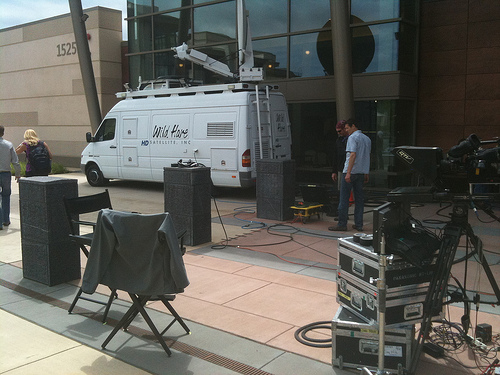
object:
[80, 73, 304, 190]
truck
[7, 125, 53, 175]
woman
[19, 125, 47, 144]
blonde hair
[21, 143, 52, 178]
bookbag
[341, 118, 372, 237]
man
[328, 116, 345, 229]
man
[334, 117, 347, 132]
bandana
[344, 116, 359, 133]
black hair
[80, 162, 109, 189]
front wheel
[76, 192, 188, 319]
coat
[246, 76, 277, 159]
ladder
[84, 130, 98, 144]
mirror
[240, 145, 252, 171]
brake light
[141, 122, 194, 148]
words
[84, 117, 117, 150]
window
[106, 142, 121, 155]
door handle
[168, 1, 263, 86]
antennae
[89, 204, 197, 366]
chair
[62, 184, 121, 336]
chair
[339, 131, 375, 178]
blue shirt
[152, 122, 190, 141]
wild hare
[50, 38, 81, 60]
number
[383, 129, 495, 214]
camera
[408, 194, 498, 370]
tripod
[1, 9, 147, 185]
building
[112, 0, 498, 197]
building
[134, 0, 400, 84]
glass windows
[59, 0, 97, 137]
pole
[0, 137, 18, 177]
shirt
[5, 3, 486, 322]
area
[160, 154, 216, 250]
box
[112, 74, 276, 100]
roof rack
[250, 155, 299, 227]
box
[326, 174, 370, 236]
jeans